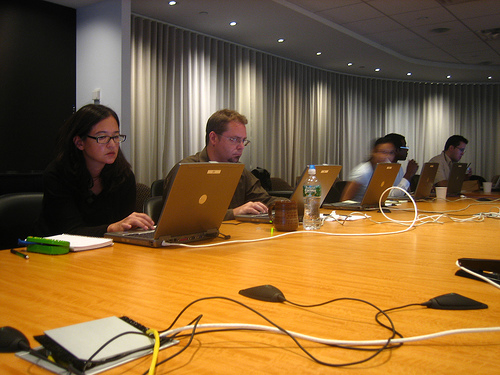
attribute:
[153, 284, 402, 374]
cord — ethernet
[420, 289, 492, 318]
mouse — black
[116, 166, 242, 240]
laptop — grey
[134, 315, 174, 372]
cord — Ethernet